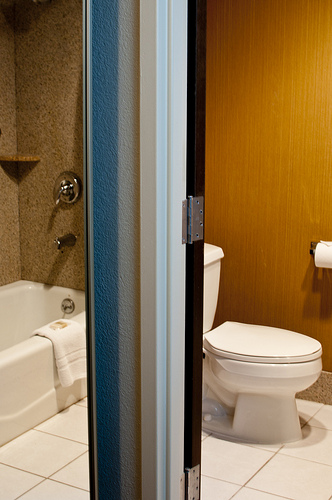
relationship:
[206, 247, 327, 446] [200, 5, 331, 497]
toilet in room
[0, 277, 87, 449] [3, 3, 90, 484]
bathtub in bathroom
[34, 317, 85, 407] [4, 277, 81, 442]
towel on bathtub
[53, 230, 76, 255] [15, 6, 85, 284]
faucet on wall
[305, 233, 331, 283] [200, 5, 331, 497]
toilet paper on wall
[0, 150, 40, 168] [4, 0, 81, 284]
shelf in wall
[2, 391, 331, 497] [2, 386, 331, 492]
tile on floor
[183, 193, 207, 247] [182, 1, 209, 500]
hinge on door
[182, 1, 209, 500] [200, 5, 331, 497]
door in room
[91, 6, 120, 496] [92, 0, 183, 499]
line on wall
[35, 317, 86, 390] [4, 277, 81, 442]
bathmat hanging on bathtub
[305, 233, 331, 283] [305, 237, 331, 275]
toilet paper on toilet paper holder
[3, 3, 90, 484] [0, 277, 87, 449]
bathroom with bathtub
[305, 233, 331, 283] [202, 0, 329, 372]
toilet paper hanging by panel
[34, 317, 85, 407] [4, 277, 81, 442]
towel hanging on bathtub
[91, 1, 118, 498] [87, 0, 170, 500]
blue on door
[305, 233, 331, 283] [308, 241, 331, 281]
toilet paper in roll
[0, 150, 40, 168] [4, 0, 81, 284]
shelf in shower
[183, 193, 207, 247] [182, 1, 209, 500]
hinge for door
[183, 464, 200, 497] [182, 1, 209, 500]
hinge for door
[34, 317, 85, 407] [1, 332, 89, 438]
towel on side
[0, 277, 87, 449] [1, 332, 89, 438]
bathtub has side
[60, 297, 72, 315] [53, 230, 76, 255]
plug under faucet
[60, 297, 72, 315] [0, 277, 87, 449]
plug for bathtub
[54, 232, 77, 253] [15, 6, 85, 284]
pipe on wall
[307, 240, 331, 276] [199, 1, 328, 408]
holder on wall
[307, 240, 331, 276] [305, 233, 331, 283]
holder for toilet paper